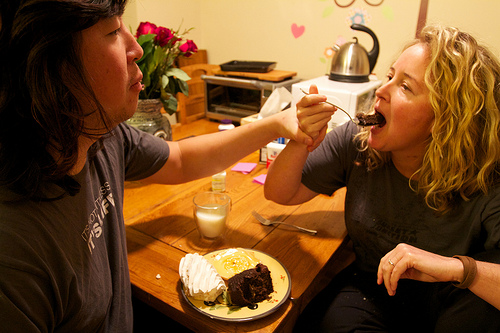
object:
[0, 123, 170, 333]
shirt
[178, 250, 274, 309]
food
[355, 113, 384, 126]
food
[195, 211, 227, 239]
milk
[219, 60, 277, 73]
cookie tray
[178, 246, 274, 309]
snacks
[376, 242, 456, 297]
hand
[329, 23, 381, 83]
kettle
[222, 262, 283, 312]
pastries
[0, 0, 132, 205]
hair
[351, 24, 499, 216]
hair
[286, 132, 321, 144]
wrist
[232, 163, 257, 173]
post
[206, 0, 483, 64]
wall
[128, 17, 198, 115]
bouquet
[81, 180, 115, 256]
writing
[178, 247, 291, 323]
plate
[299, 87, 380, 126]
fork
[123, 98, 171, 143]
vase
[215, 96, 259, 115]
tray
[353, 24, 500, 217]
head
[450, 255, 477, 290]
wristwatch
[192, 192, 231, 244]
glass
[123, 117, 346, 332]
table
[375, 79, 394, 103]
nose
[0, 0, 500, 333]
couple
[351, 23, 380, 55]
handle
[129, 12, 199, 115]
roses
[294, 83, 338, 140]
hand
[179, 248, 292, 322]
dish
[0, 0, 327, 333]
man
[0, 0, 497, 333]
two people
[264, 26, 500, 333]
woman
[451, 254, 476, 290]
bracelets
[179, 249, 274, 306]
cake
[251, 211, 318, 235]
fork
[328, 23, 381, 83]
tea pot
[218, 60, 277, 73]
tray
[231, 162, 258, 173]
note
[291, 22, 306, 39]
heart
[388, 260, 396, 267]
ring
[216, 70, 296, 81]
board